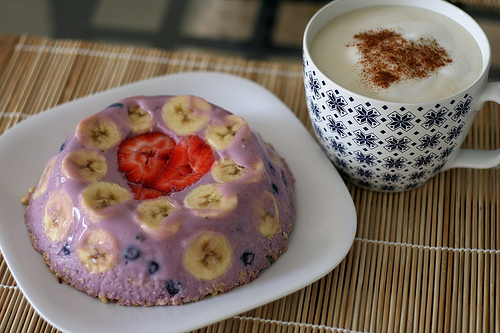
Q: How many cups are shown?
A: One.